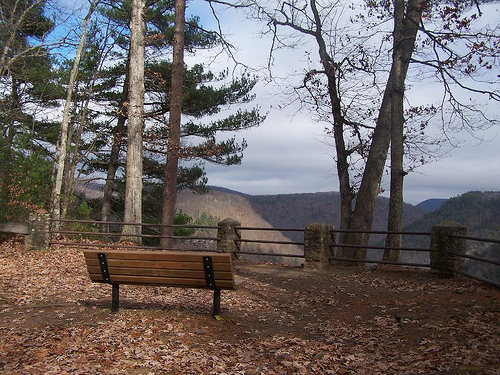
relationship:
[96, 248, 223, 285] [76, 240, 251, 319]
plates on bench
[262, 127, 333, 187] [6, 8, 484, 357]
cloud in photo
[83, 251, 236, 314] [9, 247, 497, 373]
bench on ground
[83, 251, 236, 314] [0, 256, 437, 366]
bench in ground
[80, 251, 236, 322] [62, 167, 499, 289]
bench overlooking mountains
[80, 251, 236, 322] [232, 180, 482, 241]
bench overlooking mountains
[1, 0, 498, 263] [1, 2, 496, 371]
trees in park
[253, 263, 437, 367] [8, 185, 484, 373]
ground in park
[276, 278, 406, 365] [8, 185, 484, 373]
leaves in park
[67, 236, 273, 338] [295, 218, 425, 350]
bench on ground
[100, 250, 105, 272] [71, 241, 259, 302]
screws on bench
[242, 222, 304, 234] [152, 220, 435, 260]
railings on fence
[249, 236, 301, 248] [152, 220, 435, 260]
railings on fence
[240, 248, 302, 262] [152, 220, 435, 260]
railings on fence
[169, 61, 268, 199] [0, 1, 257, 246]
branches on tree